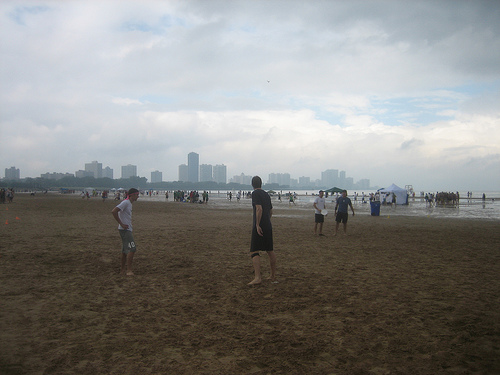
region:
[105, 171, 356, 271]
these are people playing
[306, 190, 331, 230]
the man is holding a plate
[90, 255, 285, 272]
they are bare footed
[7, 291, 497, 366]
the place is filled with sand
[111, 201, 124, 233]
the man is holding his waiste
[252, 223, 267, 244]
the man has black shorts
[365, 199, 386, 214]
this is a blue bin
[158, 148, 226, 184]
these are buildings on the far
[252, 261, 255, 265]
thew man is light skinned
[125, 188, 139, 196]
the man has tied an orange ribbon his head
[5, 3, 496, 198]
the sky is gray above the buildings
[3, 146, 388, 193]
tall buildings are above the trees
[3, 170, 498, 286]
people are on the beach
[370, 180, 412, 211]
a white canvas tent is on the beach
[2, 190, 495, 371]
the sand is brown near the water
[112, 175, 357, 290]
these boys are playing frisby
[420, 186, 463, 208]
a group of people are crowded together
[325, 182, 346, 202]
an open umbrella is on the beach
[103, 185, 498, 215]
the water at the beach is gray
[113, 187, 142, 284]
the boy is wearing a white shirt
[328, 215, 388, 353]
part of a sandy beach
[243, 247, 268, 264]
part of a black band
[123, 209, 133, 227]
a white top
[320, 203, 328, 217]
part of a white dish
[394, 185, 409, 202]
part of a white tent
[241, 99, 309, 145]
part of a cloudy sky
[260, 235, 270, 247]
part of a black pant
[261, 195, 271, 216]
part of a dark shirt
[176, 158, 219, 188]
some tall city buildings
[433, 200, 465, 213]
section of a wet ground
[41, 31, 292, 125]
Clouds are grey color.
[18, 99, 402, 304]
Day is cloudy.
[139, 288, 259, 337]
Sand is brown color.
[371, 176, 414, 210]
Tent is white color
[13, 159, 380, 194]
Buildings are seen behind the water.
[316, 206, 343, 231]
Frisbee is white color.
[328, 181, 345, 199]
One umbrella is seen.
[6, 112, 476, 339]
day time picture.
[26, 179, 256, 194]
Trees are seen behind the water.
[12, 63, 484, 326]
Picture is taken in beach.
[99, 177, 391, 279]
Boy's playing frisbee on the beach.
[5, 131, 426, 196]
City skyline is in the background.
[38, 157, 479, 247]
People hanging out on the beach.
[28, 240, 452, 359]
Sand is brown.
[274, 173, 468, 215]
Tents in the the background.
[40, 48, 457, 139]
The sky is overcast.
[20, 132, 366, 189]
Tall buildings in the background.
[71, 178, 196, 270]
Boy wearing white shirt.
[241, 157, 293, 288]
Man wearing all black.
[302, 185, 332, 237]
Frisbee in the person's hand.